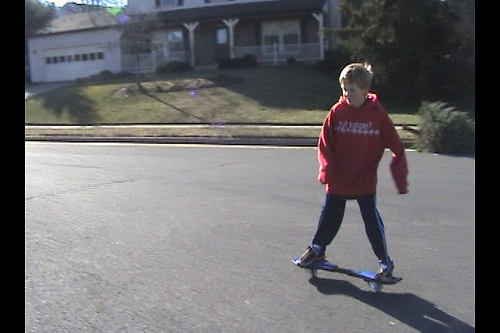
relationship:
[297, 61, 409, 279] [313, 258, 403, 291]
child on skateboard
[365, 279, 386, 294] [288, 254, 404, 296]
wheel on a ripstick